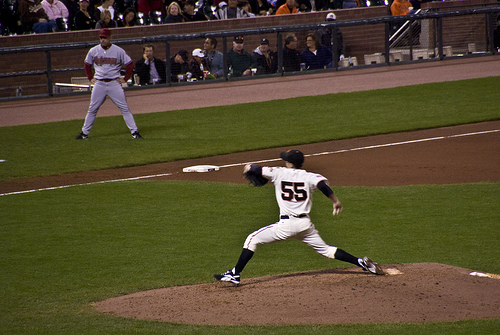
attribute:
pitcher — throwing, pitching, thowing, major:
[213, 149, 384, 287]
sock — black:
[232, 247, 253, 275]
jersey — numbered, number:
[280, 181, 309, 203]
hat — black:
[279, 146, 305, 168]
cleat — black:
[211, 271, 242, 286]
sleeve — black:
[316, 179, 334, 197]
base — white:
[181, 163, 219, 173]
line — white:
[1, 129, 497, 197]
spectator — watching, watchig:
[137, 44, 167, 84]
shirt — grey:
[83, 45, 132, 80]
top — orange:
[390, 1, 415, 17]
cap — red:
[98, 23, 111, 38]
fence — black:
[0, 5, 497, 101]